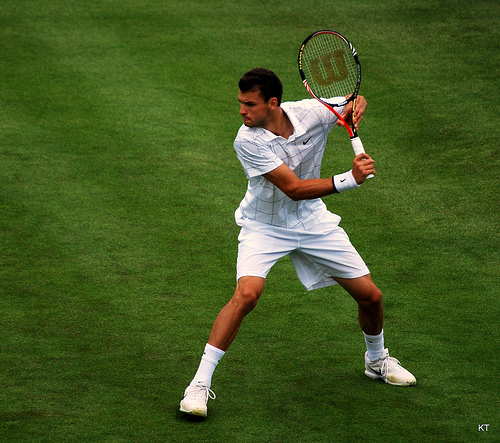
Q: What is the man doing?
A: Playing tennis.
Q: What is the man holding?
A: A tennis racket.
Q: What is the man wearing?
A: White shirt and shorts.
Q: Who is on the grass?
A: A man playing tennis.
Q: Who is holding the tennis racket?
A: A man.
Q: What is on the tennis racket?
A: A logo with the letter W.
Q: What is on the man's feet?
A: White tennis shoes.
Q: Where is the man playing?
A: On a grass tennis court.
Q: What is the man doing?
A: Playing tennis.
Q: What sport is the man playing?
A: Tennis.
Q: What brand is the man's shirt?
A: Nike.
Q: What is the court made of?
A: Grass.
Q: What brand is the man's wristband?
A: Nike.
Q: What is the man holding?
A: Tennis racquet.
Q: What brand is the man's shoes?
A: Nike.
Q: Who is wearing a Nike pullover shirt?
A: The tennis player.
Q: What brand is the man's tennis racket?
A: Nike.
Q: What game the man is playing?
A: Tennis.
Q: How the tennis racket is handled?
A: In the hands.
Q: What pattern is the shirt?
A: Squares.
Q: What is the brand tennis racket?
A: Wilson.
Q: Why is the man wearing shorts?
A: Playing tennis.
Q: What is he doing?
A: Playing tennis.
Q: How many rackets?
A: 1.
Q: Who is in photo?
A: Man.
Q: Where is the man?
A: Tennis court.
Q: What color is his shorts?
A: White.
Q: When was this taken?
A: Daytime.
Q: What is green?
A: Grass.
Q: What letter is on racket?
A: W.